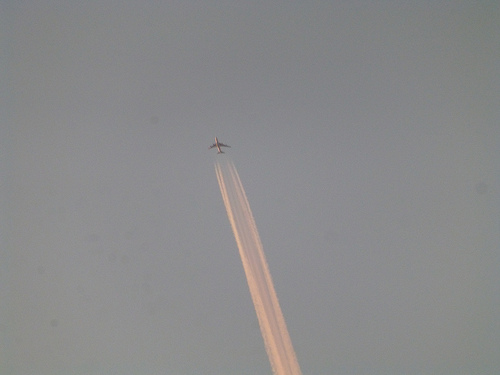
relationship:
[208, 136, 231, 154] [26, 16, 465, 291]
airplane flying in air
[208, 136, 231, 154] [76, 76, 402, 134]
airplane flying in air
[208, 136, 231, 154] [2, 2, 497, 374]
airplane flying in air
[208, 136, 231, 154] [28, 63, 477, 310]
airplane flying in air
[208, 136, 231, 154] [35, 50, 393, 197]
airplane flying in air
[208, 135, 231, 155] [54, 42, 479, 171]
airplane flying in air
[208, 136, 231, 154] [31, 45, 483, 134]
airplane flying up in air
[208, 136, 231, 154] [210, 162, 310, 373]
airplane has fumes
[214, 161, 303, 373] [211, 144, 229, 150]
streams and engines